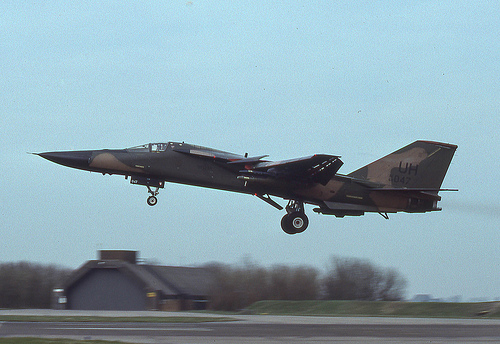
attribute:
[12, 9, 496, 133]
sky — light blue, clear 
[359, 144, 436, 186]
tail — camouflaged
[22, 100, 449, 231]
jetplane — little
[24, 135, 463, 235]
airplane — little, camoflauge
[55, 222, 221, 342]
house — small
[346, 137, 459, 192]
empennage — camouflaged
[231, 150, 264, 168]
wing — small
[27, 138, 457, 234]
jetplane — camouflage 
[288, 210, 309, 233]
wheel — back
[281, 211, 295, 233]
wheel — back